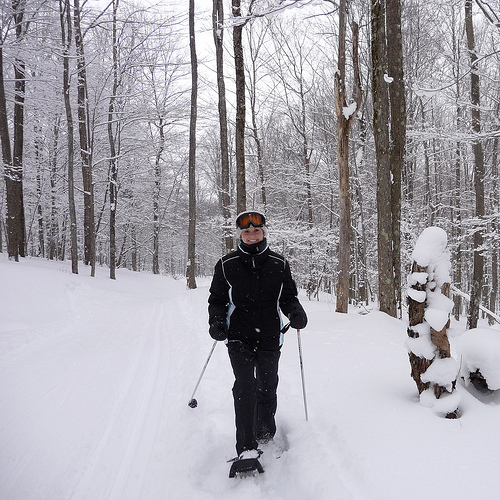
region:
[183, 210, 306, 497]
A woman walking in snow shoes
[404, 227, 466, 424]
A snow covered tree stump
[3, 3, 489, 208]
Tree branches frosted with snow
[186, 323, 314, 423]
Two walking poles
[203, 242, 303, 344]
A black and white ski jacket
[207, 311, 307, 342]
Heavy black gloves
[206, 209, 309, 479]
A smiling woman enjoying the snow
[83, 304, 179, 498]
Tracks in the snow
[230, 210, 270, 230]
Ski goggles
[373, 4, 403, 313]
Two tall tree trunks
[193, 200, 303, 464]
person skiing on snowy mountain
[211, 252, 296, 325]
person wearing black and white jacket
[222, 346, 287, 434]
person wearing black and white pants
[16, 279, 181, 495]
white snow on mountain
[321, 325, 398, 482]
white snow on mountain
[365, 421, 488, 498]
white snow on mountain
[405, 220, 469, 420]
brown stump covered in snow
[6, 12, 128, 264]
brown trees without leaves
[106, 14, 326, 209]
brown trees without leaves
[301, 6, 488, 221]
brown trees without leaves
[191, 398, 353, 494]
The woman has skis on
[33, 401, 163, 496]
The snow is white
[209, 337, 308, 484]
The woman's snow pants are black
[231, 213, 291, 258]
The woman is smiling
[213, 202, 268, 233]
The woman has goggles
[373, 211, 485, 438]
The tree is covered in snow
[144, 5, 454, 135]
The trees are tall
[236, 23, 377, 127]
The sky is cloudy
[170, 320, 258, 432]
The woman has ski poles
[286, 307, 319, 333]
The woman is wearing gloves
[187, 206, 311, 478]
woman in the snow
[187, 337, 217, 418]
black and silver snow pole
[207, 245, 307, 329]
black and white snow jacket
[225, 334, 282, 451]
black snow pants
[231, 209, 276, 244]
white snow hat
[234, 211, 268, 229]
black googles with orange lenses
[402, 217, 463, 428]
tree trunk with snow on it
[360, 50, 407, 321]
tall, brown tree trunk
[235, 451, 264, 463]
white snow boot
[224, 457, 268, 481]
black snow shoes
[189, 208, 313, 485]
Woman cross country sking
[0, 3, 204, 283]
Very tall trees on the left side of the photo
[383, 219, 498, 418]
Snow covered stump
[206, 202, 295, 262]
Goggles of womans head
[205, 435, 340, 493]
Black skis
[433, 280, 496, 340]
Small fallen tree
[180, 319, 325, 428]
Ski poles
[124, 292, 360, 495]
Snow covered roadway or path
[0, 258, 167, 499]
Snowpack on left side of roadway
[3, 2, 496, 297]
Trees without leaves lining the roadway